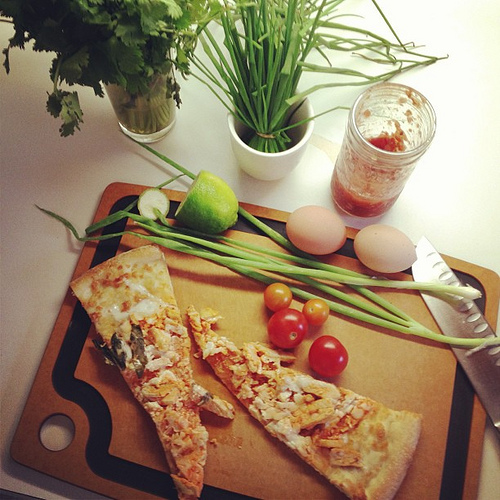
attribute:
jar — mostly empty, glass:
[331, 79, 437, 222]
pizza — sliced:
[67, 245, 210, 499]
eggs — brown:
[285, 203, 415, 274]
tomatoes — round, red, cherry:
[266, 283, 349, 380]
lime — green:
[171, 173, 241, 237]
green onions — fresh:
[35, 135, 498, 355]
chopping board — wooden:
[11, 182, 499, 499]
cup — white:
[224, 86, 314, 186]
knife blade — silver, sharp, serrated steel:
[411, 234, 499, 429]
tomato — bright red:
[311, 338, 349, 379]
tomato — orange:
[264, 280, 292, 312]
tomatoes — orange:
[263, 281, 332, 325]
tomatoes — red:
[268, 309, 348, 376]